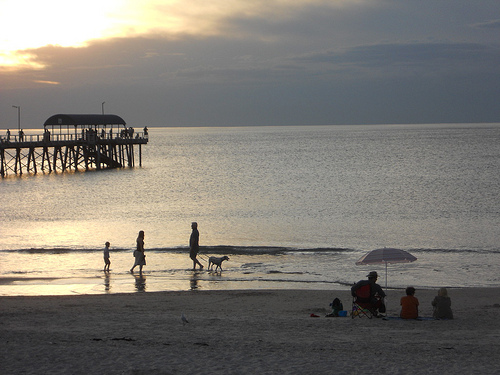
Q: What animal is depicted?
A: Dog.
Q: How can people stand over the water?
A: Dock on left.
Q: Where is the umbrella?
A: On shore.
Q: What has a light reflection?
A: Water.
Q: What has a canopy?
A: Dock.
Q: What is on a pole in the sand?
A: Umbrella.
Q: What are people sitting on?
A: Sand.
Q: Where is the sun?
A: Top left.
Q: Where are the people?
A: At the beach.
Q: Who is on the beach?
A: Some people.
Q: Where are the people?
A: On the beach.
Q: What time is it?
A: Evening.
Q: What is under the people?
A: Sand.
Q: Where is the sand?
A: On the beach.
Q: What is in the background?
A: Water.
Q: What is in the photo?
A: A dog.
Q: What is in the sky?
A: Clouds.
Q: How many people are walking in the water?
A: Three.